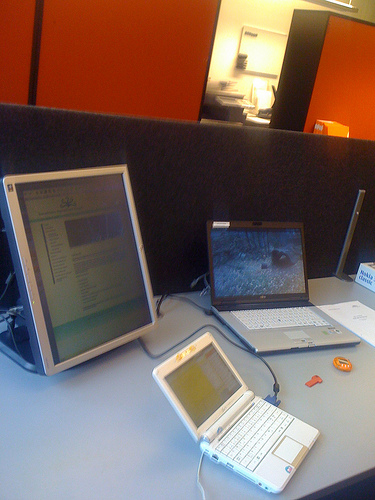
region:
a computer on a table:
[123, 260, 322, 492]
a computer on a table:
[215, 359, 347, 497]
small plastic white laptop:
[171, 322, 319, 498]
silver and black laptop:
[208, 222, 356, 355]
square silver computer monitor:
[28, 168, 142, 360]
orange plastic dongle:
[303, 370, 325, 391]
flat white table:
[62, 393, 154, 498]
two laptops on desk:
[172, 220, 354, 486]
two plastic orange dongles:
[294, 356, 359, 390]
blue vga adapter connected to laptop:
[256, 391, 283, 407]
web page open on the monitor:
[33, 185, 151, 336]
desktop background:
[216, 228, 302, 293]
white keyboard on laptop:
[246, 305, 329, 324]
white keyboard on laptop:
[230, 404, 264, 469]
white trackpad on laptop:
[276, 439, 300, 466]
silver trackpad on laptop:
[283, 328, 310, 340]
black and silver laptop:
[210, 222, 362, 350]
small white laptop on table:
[168, 354, 314, 493]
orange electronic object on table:
[328, 353, 355, 376]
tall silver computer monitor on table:
[0, 160, 164, 375]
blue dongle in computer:
[262, 392, 283, 408]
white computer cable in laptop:
[187, 456, 213, 495]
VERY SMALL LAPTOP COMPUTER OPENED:
[142, 335, 337, 494]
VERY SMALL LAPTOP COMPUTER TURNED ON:
[139, 325, 317, 498]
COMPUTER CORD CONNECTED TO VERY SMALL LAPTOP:
[181, 320, 332, 437]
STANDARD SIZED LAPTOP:
[202, 213, 365, 381]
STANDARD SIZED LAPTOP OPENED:
[185, 211, 371, 391]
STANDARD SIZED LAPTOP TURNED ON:
[202, 216, 355, 363]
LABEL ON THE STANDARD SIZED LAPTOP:
[195, 214, 256, 241]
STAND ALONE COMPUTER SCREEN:
[4, 173, 214, 399]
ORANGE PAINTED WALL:
[283, 11, 373, 165]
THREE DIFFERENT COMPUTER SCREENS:
[0, 162, 373, 465]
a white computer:
[145, 321, 327, 496]